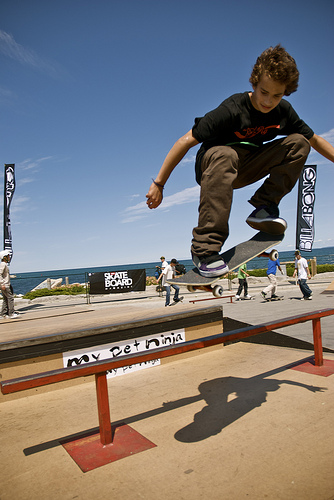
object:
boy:
[145, 46, 334, 279]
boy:
[235, 264, 250, 296]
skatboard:
[165, 230, 284, 297]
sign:
[65, 328, 182, 377]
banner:
[89, 269, 146, 293]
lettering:
[104, 271, 133, 291]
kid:
[0, 249, 20, 320]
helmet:
[0, 249, 13, 262]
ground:
[1, 270, 333, 498]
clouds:
[121, 186, 198, 221]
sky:
[1, 1, 333, 251]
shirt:
[238, 264, 247, 280]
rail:
[170, 308, 317, 346]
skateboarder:
[264, 296, 284, 302]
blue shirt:
[266, 260, 280, 276]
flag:
[296, 162, 317, 251]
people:
[155, 248, 312, 304]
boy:
[292, 249, 314, 300]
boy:
[154, 257, 180, 307]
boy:
[154, 257, 168, 297]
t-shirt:
[295, 258, 308, 280]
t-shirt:
[265, 259, 280, 275]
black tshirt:
[191, 90, 315, 190]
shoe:
[189, 247, 228, 279]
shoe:
[245, 206, 287, 233]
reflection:
[173, 374, 327, 443]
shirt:
[161, 265, 175, 288]